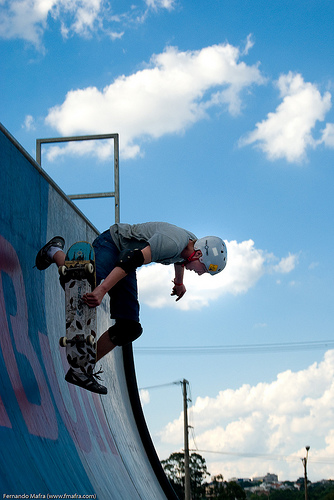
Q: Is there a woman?
A: No, there are no women.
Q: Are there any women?
A: No, there are no women.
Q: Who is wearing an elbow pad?
A: The skater is wearing an elbow pad.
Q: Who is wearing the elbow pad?
A: The skater is wearing an elbow pad.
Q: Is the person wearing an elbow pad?
A: Yes, the skater is wearing an elbow pad.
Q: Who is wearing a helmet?
A: The skater is wearing a helmet.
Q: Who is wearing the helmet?
A: The skater is wearing a helmet.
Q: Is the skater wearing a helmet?
A: Yes, the skater is wearing a helmet.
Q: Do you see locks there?
A: No, there are no locks.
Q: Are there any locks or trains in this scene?
A: No, there are no locks or trains.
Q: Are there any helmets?
A: Yes, there is a helmet.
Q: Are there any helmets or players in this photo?
A: Yes, there is a helmet.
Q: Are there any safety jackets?
A: No, there are no safety jackets.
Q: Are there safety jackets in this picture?
A: No, there are no safety jackets.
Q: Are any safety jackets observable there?
A: No, there are no safety jackets.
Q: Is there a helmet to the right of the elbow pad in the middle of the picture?
A: Yes, there is a helmet to the right of the elbow pad.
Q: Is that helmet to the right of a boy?
A: No, the helmet is to the right of the elbow pad.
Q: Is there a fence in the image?
A: No, there are no fences.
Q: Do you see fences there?
A: No, there are no fences.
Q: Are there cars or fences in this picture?
A: No, there are no fences or cars.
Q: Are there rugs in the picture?
A: No, there are no rugs.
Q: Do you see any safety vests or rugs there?
A: No, there are no rugs or safety vests.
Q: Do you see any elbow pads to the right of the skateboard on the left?
A: Yes, there is an elbow pad to the right of the skateboard.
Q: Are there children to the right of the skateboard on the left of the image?
A: No, there is an elbow pad to the right of the skateboard.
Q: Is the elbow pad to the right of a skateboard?
A: Yes, the elbow pad is to the right of a skateboard.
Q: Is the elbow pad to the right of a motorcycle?
A: No, the elbow pad is to the right of a skateboard.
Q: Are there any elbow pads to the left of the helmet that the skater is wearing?
A: Yes, there is an elbow pad to the left of the helmet.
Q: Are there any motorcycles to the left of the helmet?
A: No, there is an elbow pad to the left of the helmet.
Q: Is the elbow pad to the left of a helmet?
A: Yes, the elbow pad is to the left of a helmet.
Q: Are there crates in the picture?
A: No, there are no crates.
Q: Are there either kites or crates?
A: No, there are no crates or kites.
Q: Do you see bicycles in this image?
A: No, there are no bicycles.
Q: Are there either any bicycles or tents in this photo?
A: No, there are no bicycles or tents.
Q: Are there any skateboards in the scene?
A: Yes, there is a skateboard.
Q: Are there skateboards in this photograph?
A: Yes, there is a skateboard.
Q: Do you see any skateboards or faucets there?
A: Yes, there is a skateboard.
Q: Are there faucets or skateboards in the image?
A: Yes, there is a skateboard.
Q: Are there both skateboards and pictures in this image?
A: No, there is a skateboard but no pictures.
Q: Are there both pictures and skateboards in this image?
A: No, there is a skateboard but no pictures.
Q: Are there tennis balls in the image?
A: No, there are no tennis balls.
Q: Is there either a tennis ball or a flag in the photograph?
A: No, there are no tennis balls or flags.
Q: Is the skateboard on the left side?
A: Yes, the skateboard is on the left of the image.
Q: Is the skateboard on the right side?
A: No, the skateboard is on the left of the image.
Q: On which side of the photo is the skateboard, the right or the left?
A: The skateboard is on the left of the image.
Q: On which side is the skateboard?
A: The skateboard is on the left of the image.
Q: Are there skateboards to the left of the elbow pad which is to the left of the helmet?
A: Yes, there is a skateboard to the left of the elbow pad.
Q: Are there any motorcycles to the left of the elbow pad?
A: No, there is a skateboard to the left of the elbow pad.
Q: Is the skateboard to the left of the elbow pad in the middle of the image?
A: Yes, the skateboard is to the left of the elbow pad.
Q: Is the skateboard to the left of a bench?
A: No, the skateboard is to the left of the elbow pad.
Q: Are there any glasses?
A: No, there are no glasses.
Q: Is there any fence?
A: No, there are no fences.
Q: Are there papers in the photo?
A: No, there are no papers.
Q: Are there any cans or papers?
A: No, there are no papers or cans.